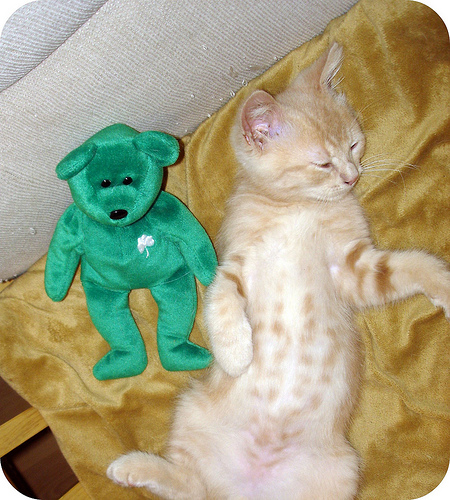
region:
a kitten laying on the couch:
[100, 43, 449, 494]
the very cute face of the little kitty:
[225, 46, 362, 207]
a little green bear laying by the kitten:
[45, 124, 218, 383]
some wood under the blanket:
[3, 387, 71, 498]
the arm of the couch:
[3, 0, 347, 272]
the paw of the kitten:
[105, 448, 201, 498]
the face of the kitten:
[296, 134, 366, 205]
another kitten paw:
[208, 306, 253, 374]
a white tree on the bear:
[135, 230, 152, 260]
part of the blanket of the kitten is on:
[381, 309, 440, 494]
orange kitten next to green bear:
[34, 81, 352, 492]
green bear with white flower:
[52, 95, 215, 388]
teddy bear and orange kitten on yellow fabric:
[16, 33, 436, 474]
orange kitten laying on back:
[199, 50, 397, 476]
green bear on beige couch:
[10, 28, 276, 246]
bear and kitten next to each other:
[55, 64, 421, 452]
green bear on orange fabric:
[52, 114, 264, 463]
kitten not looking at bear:
[32, 129, 446, 446]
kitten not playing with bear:
[39, 78, 384, 497]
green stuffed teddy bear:
[48, 96, 212, 373]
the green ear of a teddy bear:
[132, 122, 184, 174]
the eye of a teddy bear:
[120, 169, 136, 187]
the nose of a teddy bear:
[101, 200, 137, 225]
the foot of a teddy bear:
[154, 336, 217, 373]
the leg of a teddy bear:
[150, 269, 202, 342]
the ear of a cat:
[229, 87, 284, 153]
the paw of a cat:
[211, 328, 261, 380]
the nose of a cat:
[342, 170, 362, 189]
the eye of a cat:
[344, 131, 362, 153]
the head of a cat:
[224, 37, 371, 213]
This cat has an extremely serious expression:
[280, 117, 402, 224]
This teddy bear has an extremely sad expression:
[77, 140, 145, 246]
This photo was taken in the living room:
[78, 100, 360, 464]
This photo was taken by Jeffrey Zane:
[52, 95, 338, 496]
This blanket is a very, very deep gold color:
[399, 179, 415, 211]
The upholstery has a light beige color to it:
[156, 46, 175, 91]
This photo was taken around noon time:
[85, 73, 347, 458]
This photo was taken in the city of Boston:
[73, 21, 379, 427]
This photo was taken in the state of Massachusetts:
[79, 108, 345, 447]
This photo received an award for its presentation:
[90, 133, 349, 461]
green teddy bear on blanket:
[38, 111, 240, 391]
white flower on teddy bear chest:
[134, 231, 165, 261]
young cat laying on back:
[173, 46, 412, 451]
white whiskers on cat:
[365, 140, 415, 188]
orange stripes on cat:
[343, 233, 400, 304]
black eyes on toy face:
[93, 172, 139, 191]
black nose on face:
[101, 206, 133, 226]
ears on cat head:
[234, 39, 361, 148]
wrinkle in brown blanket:
[392, 110, 442, 190]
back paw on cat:
[102, 446, 185, 493]